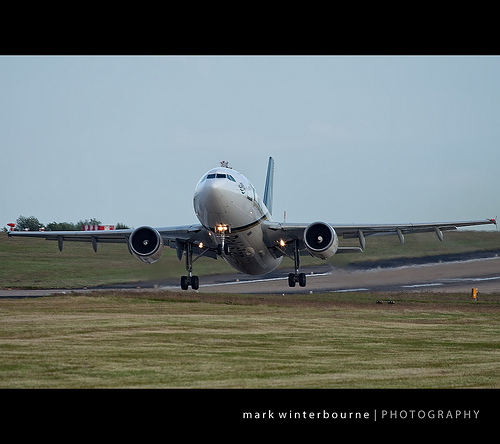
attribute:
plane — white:
[8, 137, 492, 292]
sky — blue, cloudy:
[96, 70, 133, 121]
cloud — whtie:
[333, 95, 361, 112]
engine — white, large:
[294, 215, 351, 261]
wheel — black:
[288, 265, 314, 293]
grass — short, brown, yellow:
[80, 331, 125, 362]